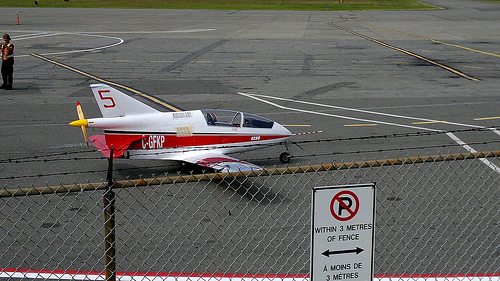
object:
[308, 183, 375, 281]
sign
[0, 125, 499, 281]
fence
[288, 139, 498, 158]
wire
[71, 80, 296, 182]
plane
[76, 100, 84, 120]
propeller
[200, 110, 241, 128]
cockpit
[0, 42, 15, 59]
vest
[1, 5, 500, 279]
runway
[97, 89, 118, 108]
number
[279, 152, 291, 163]
wheel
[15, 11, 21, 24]
cone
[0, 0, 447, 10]
grass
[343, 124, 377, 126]
stripe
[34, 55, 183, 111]
line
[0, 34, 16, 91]
man